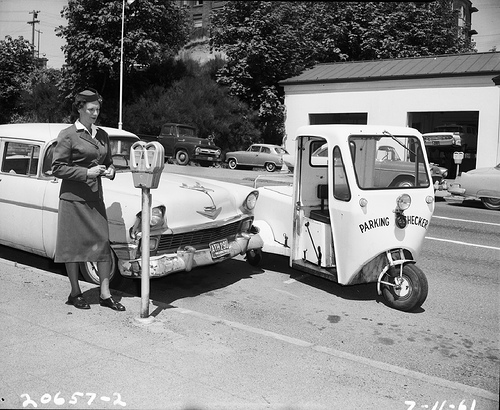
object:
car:
[422, 131, 469, 146]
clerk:
[48, 89, 126, 312]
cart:
[244, 124, 449, 314]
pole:
[26, 8, 46, 59]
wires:
[0, 6, 64, 44]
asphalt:
[137, 330, 391, 410]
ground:
[438, 213, 461, 262]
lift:
[418, 145, 459, 175]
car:
[0, 122, 263, 286]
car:
[225, 144, 290, 172]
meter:
[453, 151, 466, 176]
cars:
[137, 122, 221, 168]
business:
[267, 41, 499, 226]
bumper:
[116, 230, 264, 278]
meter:
[129, 140, 164, 189]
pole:
[138, 186, 152, 317]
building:
[277, 50, 500, 180]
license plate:
[208, 238, 231, 259]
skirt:
[54, 198, 113, 265]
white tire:
[176, 150, 191, 166]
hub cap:
[180, 154, 185, 161]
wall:
[287, 85, 499, 110]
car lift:
[426, 148, 474, 163]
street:
[0, 151, 500, 410]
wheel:
[379, 262, 427, 313]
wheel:
[246, 232, 262, 266]